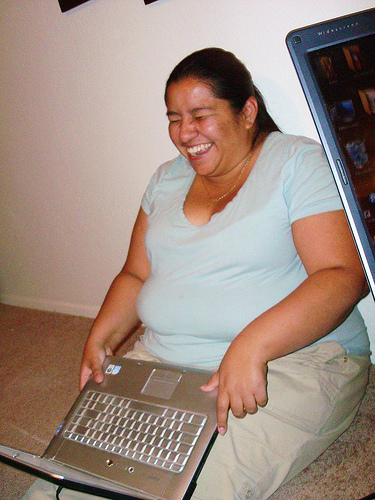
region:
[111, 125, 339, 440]
Woman holding laptop in her lap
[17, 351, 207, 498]
Silver personal computer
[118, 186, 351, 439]
Woman wearing light blue shirt and khaki pants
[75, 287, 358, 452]
Woman sitting on the floor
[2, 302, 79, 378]
Beige carpeted floor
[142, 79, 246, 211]
Woman smiling and laughing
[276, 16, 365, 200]
The corner of the screen of a light blue laptop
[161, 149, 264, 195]
Woman wearing gold necklace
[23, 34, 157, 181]
Walls are painted white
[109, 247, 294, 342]
Woman is a little overweight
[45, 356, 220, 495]
woman has silver laptop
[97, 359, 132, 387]
stickers on silver laptop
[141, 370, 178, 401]
touchpad on laptop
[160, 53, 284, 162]
woman has brown hair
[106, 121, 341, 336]
woman wears light blue shirt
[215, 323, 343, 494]
woman wears khaki pants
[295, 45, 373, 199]
camera phone taking picture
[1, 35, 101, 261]
wall is creamy white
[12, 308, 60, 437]
floor is light brown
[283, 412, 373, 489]
woman sitting on chair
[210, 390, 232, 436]
a finger of a hand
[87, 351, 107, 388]
a thumb of a hand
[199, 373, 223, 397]
a thumb of a hand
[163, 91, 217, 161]
a face with a smile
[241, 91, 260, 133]
an ear of a person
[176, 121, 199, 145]
a nose of a person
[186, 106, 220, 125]
an eye of a person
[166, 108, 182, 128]
an eye of a person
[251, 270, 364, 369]
an arm of a person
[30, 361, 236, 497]
a laptop on a lap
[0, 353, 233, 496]
a silver laptop in the picture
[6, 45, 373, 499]
the woman is fat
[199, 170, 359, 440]
the hand of the woman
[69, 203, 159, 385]
the hand of the woman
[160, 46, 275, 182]
the head of the woman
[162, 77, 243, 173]
the woman is laughing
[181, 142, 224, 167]
the mouth of the woman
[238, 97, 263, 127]
the ear of the woman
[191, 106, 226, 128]
the eye of the woman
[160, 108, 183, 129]
the eye of the woman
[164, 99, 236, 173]
Woman in the foreground is smiling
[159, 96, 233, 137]
Woman has her eyes closed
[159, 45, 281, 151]
Woman has dark colored hair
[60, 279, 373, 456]
Woman is sitting on the carpet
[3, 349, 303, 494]
Woman is holding a laptop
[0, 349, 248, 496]
The laptop is gray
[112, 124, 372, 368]
Woman is wearing a light blue shirt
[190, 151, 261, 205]
Woman is wearing a gold necklace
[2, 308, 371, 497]
The carpet is tan colored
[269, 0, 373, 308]
The side angle of an electronic device